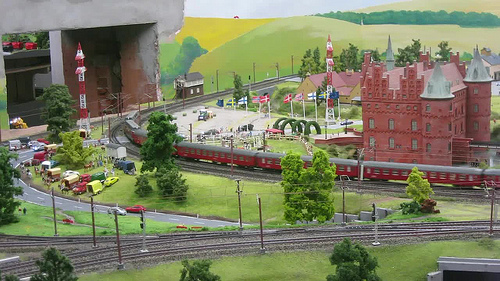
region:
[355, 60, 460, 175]
The building is brick.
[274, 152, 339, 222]
The trees are leafy.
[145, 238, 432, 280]
The grass is green.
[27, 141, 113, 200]
The vehicles are parked.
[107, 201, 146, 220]
The cars are on the road.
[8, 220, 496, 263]
The street is grey.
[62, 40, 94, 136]
The tower is red and white.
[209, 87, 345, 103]
The flags are different colors.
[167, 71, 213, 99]
The house is brown and white.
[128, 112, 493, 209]
The train is red.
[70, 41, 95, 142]
Red and white metal tower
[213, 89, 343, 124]
Ten flags on flagpoles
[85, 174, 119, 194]
Bright green car with trailer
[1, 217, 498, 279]
Four converging railroads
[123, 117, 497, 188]
A long, moving red train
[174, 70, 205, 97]
Brown and white two story station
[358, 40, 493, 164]
Red, castle-like building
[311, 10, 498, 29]
Trees on a hill in the far background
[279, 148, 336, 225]
Bright green tree near a railroad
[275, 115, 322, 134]
Four hedge archways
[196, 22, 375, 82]
the hill in the background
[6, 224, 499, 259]
the railway tracks in the picture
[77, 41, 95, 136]
the tower on the lefthand side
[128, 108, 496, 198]
the train by the buildings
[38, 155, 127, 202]
the cars by the side of the road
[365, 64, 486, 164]
the big brick tower building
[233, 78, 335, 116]
the flags showing on the posts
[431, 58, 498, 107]
the gray towers on the building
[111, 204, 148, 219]
the two cars on the road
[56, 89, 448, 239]
the trees at the bottom of the picture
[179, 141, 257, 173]
red and gray train wagon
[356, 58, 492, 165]
a big red castle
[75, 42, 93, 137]
a white and red tower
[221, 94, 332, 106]
flags of different countries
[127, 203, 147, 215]
a red car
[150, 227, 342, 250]
the railroad tracks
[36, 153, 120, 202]
vehicles of different colors and shapes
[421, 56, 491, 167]
the two towers of the castle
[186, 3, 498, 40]
mountains in the distance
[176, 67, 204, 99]
train control booth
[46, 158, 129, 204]
the cars are parked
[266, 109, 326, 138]
the tiresa re rubber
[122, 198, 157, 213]
the car is red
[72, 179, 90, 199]
the car is red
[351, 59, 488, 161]
the castle is red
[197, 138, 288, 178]
the train is on the move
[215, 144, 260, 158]
the rrtrain is red and grey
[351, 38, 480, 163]
the castle has four towers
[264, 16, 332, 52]
hill is in the background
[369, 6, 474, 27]
trees are in the background